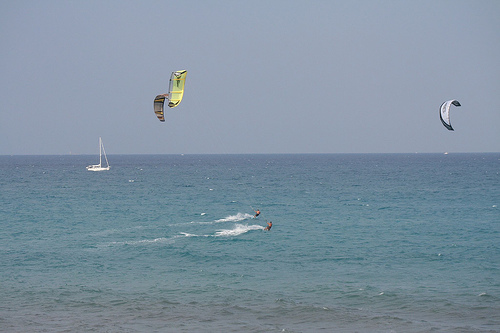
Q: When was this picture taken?
A: Daytime.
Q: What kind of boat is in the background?
A: Sailboat.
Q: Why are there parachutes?
A: To parasail.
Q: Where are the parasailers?
A: In the water.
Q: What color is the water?
A: Blue.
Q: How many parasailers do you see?
A: Two.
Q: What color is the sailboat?
A: White.